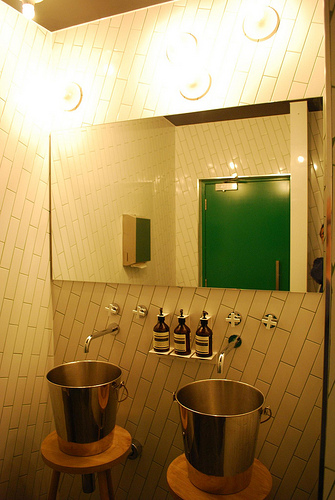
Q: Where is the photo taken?
A: Bathroom.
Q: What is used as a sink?
A: Buckets.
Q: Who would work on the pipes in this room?
A: Plumber.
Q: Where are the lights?
A: Above the mirror.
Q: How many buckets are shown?
A: Two.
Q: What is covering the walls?
A: Tile.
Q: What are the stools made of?
A: Wood.